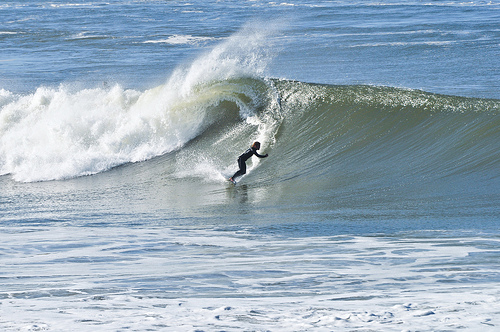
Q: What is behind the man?
A: A wave.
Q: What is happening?
A: Surfer surfing.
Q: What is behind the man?
A: Crashing wave.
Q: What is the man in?
A: Ocean.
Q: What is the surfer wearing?
A: Wet suit.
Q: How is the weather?
A: Sunnt.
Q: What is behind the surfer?
A: Cap curling.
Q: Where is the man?
A: In the water.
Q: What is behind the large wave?
A: White caps.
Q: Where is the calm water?
A: In the distance.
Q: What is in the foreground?
A: Calm water.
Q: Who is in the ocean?
A: A surfer.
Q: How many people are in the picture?
A: One.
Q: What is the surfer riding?
A: A wave.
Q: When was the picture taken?
A: Daytime.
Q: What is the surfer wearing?
A: Wetsuit.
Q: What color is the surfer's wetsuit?
A: Black.